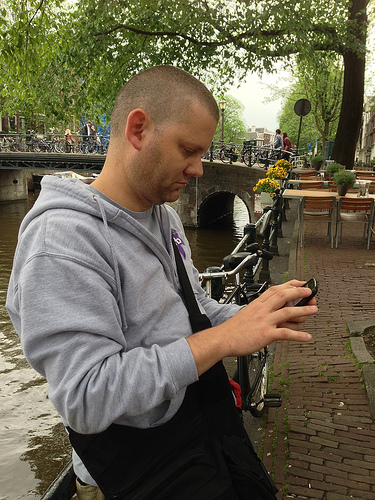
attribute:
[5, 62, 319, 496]
man — shaved head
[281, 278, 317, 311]
phone — small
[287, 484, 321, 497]
brick — red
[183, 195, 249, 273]
water — here, dirty, brown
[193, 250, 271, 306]
bike — here, leaning, parked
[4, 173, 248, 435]
sweatshirt — grey, gray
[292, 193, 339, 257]
chair — here, brown, wooden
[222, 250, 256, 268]
seat — black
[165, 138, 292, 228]
bridge — stone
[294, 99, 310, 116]
sign — traffic sign, metal, rounded, round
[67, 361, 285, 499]
bag — fabric, black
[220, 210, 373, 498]
walkway — brick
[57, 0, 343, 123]
branch — large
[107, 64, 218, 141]
hair — buzzed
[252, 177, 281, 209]
flower — yellow, potted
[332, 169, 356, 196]
plant — green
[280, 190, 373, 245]
table — wood